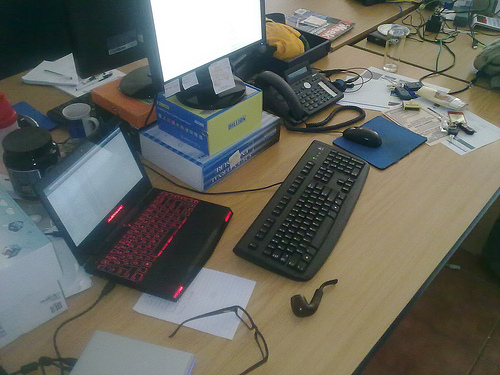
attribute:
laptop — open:
[37, 109, 247, 305]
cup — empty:
[61, 100, 98, 141]